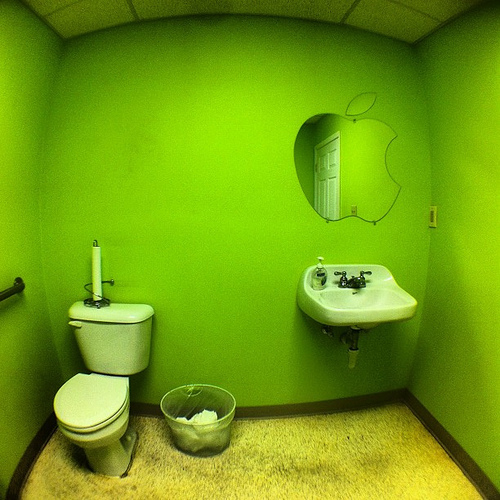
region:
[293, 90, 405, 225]
a mirror on a wall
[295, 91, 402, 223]
a mirror whaped like an apple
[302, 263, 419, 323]
a white sink on the wall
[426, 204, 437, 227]
an outlet on the wall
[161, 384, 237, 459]
a trash can beside the toilet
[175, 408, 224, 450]
trash in the trash can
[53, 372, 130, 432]
the seat of a toilet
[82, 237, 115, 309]
a paper towel holder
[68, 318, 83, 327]
the handle of a toilet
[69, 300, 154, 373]
the tank of a toilet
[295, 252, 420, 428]
a wash basin mounted on the green wall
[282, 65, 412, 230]
an apple shaped mirror on the wall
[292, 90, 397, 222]
reflection of a door in the mirror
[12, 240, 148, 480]
a toilet at the corner of the room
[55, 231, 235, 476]
basket is kept next to the toilet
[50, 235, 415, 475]
a basket is in between toilet and wash basin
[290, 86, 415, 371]
a mirror is above the wash basin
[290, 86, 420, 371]
a wash basin is mounted below the mirror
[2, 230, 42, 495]
a bar is fixed horizontally on the wall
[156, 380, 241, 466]
a basket is placed on the floor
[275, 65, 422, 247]
apple shaped mirror on wall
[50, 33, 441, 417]
neon green bathroom wall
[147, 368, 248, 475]
wastebasket in bathroom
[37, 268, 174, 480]
white ceramic porcelain bowl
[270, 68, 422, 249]
reflection of bathroom door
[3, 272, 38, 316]
rod hung on wall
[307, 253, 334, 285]
soap dispenser on sink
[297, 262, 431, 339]
white ceramic sink and faucet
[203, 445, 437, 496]
tan scratchy bathroom floor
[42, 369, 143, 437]
lid of white toilet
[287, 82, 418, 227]
mirror on the wall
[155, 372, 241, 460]
trash can in the bathroom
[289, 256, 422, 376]
sink on the wall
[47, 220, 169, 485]
toilet in the bathroom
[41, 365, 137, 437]
toilet seat on a toilet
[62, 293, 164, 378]
toilet tank on a toilet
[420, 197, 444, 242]
switch on the wall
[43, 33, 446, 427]
paint on the wall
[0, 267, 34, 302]
grab bar on the wall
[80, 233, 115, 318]
paper towel holder on the toilet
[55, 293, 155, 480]
white toilet in green bathroom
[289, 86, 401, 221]
apple mirror in green bathroom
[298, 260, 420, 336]
white handwash on green bathroom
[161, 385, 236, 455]
green bin on green bathroom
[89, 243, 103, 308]
large white candle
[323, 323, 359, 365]
gray metal pipeline of handwash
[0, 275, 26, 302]
black handle in green wall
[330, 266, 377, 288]
gray metal taps in handwash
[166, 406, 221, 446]
white papers on the bin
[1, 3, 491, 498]
green wall in bathrooms